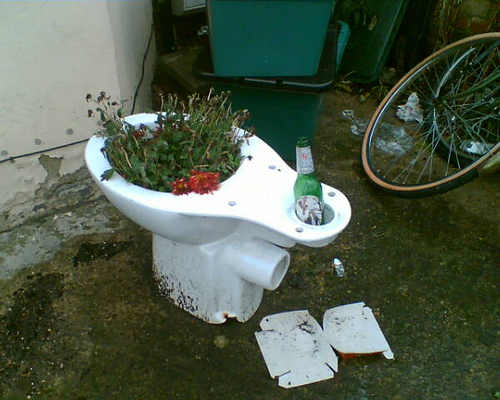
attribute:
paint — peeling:
[0, 117, 111, 221]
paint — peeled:
[2, 154, 97, 271]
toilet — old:
[65, 96, 372, 351]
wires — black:
[1, 22, 156, 163]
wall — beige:
[1, 0, 157, 236]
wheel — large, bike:
[353, 33, 498, 216]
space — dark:
[149, 0, 211, 77]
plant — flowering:
[79, 82, 257, 198]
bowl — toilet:
[99, 117, 262, 193]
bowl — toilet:
[106, 107, 239, 197]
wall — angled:
[12, 21, 176, 158]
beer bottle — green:
[291, 135, 323, 225]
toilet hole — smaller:
[293, 196, 333, 230]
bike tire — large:
[350, 25, 496, 198]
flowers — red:
[170, 165, 218, 196]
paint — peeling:
[32, 151, 91, 213]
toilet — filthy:
[84, 107, 352, 324]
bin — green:
[228, 16, 354, 147]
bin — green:
[206, 1, 339, 80]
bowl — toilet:
[101, 120, 247, 192]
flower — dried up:
[169, 176, 189, 198]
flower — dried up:
[194, 172, 214, 192]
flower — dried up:
[98, 90, 108, 100]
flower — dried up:
[156, 87, 166, 97]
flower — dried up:
[244, 120, 254, 145]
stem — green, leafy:
[104, 117, 136, 170]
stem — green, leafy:
[156, 98, 166, 138]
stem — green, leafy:
[221, 134, 242, 167]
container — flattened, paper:
[256, 299, 407, 391]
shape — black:
[72, 240, 133, 272]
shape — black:
[4, 269, 69, 354]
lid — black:
[196, 19, 340, 97]